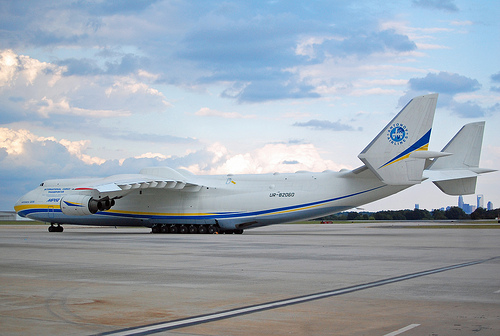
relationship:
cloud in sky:
[0, 0, 499, 173] [157, 98, 270, 129]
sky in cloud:
[0, 2, 500, 211] [0, 0, 499, 173]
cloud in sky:
[0, 0, 499, 173] [0, 2, 499, 222]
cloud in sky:
[0, 49, 178, 128] [0, 2, 499, 222]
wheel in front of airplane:
[49, 224, 55, 232] [13, 92, 497, 234]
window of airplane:
[40, 183, 43, 185] [13, 92, 497, 234]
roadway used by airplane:
[73, 236, 270, 323] [40, 113, 460, 278]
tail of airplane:
[366, 98, 493, 212] [11, 87, 495, 259]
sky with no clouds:
[158, 67, 284, 104] [5, 52, 123, 130]